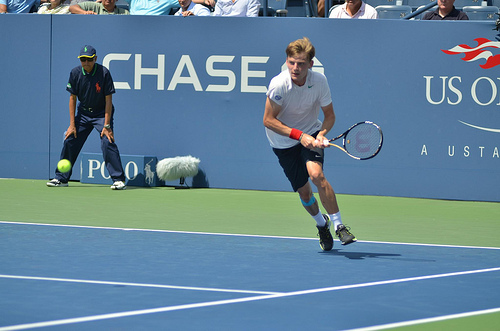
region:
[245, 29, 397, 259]
man playing tennis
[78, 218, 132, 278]
blue and white tennis court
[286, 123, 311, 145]
THIS IS A WRIST BAND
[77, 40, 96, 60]
THIS IS A CAP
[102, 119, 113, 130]
THIS IS A WATCH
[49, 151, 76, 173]
THIS IS A BALL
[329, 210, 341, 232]
THIS IS A SOCK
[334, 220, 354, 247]
THIS IS A SHOE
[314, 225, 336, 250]
THIS IS A SHOE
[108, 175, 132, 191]
THIS IS A SHOE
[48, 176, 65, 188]
THIS IS A SHOE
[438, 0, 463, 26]
this is a person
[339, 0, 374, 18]
this is a person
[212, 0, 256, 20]
this is a person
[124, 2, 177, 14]
this is a person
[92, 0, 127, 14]
this is a person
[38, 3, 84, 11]
this is a person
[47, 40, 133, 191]
linesman watching yellow ball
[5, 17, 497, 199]
blue wall with sponsor and tournament name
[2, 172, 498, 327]
blue and white court within green surface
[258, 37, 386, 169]
player holding racket with both hands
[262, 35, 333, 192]
player wearing black and white outfit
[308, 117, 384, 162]
player holding black and white racket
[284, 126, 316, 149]
red sweatband over wrist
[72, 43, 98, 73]
linesman in cap and sunglasses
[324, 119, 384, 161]
man holding black tennis racket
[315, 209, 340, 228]
man wearing white socks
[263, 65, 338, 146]
man wearing white shirt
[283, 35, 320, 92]
man with short blond hair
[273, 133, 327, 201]
man wearing black shorts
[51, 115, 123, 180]
man wearing blue pants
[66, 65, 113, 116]
umpire wearing blue shirt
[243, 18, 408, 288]
this is a man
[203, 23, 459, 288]
the man is running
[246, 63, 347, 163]
man wearing a white shirt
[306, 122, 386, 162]
the man is holding a racket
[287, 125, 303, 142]
the man is wearing a wrist band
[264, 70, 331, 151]
the t shirt is white in color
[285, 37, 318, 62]
the man has light brown hair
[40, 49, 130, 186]
the man is standint with legs spread wide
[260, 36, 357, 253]
Tennis player wearing white shirt and black shorts.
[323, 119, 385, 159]
Wilson brand tennis racket rimmed in black and white.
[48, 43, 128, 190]
Man wearing dark blue denim jeans.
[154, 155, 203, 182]
Furry white protective covering for microphone.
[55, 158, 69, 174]
Fuzzy neon lime green tennis ball in air.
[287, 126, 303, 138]
Bright red terry cloth sweat band.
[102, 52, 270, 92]
Chase bank logo in white capital letters.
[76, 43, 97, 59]
Ralph Lauren baseball cap with green horse logo.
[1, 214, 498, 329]
White lines on blue tennis court.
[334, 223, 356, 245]
Black athletic sneaker with laces tied.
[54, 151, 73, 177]
The green ball is in the air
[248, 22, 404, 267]
The man is holding a tennis racket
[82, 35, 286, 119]
The letters are white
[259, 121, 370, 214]
The shorts are black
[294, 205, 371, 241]
The socks are white